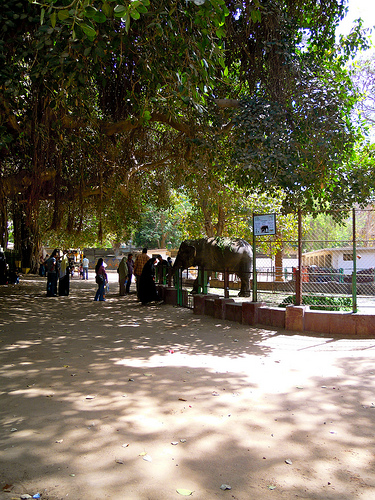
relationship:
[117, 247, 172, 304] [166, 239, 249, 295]
people standing near elephant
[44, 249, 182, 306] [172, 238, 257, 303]
people standing in front of elephant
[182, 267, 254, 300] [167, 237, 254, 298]
fence between elephant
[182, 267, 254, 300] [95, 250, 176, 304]
fence between people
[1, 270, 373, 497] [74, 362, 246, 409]
ground has shadow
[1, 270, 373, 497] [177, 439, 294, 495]
ground has shadow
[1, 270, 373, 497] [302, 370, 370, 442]
ground has shadow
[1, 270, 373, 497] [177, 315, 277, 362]
ground has shadow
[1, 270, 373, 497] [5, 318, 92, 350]
ground has shadow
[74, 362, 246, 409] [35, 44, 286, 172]
shadow cast by trees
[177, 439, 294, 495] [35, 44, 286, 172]
shadow cast by trees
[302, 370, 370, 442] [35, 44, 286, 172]
shadow cast by trees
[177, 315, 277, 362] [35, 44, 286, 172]
shadow cast by trees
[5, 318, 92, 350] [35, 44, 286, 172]
shadow cast by trees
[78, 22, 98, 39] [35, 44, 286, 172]
leaf of trees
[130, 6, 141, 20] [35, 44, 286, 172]
leaf of trees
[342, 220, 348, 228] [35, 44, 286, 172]
leaf of trees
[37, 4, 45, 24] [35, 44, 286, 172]
leaf of trees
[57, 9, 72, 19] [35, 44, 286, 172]
leaf of trees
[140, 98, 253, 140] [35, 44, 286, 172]
branch of trees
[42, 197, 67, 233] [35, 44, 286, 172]
branch of trees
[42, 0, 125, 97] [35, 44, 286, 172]
branch of trees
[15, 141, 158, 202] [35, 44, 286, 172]
branch of trees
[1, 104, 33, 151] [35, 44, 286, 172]
branch of trees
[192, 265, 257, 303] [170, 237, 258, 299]
fat legs of animal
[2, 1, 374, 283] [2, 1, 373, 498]
trees over park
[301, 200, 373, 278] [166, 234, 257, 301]
building in back elephant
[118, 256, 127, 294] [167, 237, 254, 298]
person standing close to elephant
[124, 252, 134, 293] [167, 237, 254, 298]
person standing close to elephant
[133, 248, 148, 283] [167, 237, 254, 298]
person standing close to elephant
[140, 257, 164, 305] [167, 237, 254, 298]
person standing close to elephant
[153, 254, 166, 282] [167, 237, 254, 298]
person standing close to elephant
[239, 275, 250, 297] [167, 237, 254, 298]
fat legs of elephant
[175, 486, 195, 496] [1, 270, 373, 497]
leaf on ground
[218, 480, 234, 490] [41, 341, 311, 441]
leaf on ground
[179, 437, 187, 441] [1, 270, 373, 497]
leaf on ground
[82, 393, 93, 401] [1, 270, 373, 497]
leaf on ground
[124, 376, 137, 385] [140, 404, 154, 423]
leaf on ground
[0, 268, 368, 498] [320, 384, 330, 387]
dirt are spread on leaves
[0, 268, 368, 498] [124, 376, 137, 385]
dirt are spread on leaf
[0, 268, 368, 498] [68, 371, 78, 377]
dirt are spread on leaves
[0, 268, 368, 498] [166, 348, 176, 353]
dirt are spread on leaves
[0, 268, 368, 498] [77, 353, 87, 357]
dirt are spread on leaves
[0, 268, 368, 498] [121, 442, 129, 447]
dirt are spread on leaves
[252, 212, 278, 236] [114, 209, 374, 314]
sign on fence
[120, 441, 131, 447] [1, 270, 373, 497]
leaf on ground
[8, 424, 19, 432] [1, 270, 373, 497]
leaf on ground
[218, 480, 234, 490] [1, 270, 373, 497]
leaf on ground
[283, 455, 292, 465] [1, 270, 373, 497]
leaf on ground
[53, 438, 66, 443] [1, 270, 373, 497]
leaf on ground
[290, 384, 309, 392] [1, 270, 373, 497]
leaf on ground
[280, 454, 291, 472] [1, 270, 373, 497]
leaf on ground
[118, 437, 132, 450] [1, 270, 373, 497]
leaf on ground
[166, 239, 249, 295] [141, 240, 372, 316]
elephant in fence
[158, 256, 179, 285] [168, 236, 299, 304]
trunk of a elephant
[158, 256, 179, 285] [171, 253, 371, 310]
trunk reaching outside fence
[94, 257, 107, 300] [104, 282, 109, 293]
woman carrying water bottle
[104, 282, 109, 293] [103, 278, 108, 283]
water bottle in her hand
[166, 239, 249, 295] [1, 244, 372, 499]
elephant at park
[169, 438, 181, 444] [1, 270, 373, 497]
leaf on ground